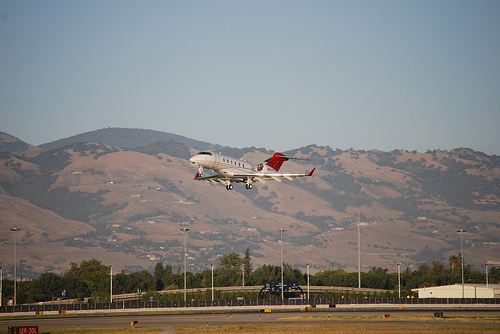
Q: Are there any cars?
A: No, there are no cars.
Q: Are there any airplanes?
A: Yes, there is an airplane.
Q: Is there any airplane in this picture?
A: Yes, there is an airplane.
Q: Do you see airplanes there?
A: Yes, there is an airplane.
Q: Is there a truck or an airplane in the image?
A: Yes, there is an airplane.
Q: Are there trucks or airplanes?
A: Yes, there is an airplane.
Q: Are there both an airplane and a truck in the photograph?
A: No, there is an airplane but no trucks.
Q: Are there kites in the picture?
A: No, there are no kites.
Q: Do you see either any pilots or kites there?
A: No, there are no kites or pilots.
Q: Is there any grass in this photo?
A: Yes, there is grass.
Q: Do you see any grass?
A: Yes, there is grass.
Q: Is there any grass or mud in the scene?
A: Yes, there is grass.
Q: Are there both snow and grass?
A: No, there is grass but no snow.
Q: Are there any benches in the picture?
A: No, there are no benches.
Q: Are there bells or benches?
A: No, there are no benches or bells.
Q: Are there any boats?
A: No, there are no boats.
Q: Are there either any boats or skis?
A: No, there are no boats or skis.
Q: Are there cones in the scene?
A: No, there are no cones.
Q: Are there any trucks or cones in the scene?
A: No, there are no cones or trucks.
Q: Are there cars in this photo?
A: No, there are no cars.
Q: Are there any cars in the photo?
A: No, there are no cars.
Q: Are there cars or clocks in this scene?
A: No, there are no cars or clocks.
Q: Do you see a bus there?
A: No, there are no buses.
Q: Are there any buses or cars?
A: No, there are no buses or cars.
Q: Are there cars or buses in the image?
A: No, there are no buses or cars.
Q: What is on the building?
A: The sign is on the building.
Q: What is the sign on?
A: The sign is on the building.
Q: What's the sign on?
A: The sign is on the building.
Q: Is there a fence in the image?
A: Yes, there is a fence.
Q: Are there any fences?
A: Yes, there is a fence.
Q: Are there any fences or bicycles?
A: Yes, there is a fence.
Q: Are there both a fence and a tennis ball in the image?
A: No, there is a fence but no tennis balls.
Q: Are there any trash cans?
A: No, there are no trash cans.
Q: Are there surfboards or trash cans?
A: No, there are no trash cans or surfboards.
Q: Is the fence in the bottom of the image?
A: Yes, the fence is in the bottom of the image.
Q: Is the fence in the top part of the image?
A: No, the fence is in the bottom of the image.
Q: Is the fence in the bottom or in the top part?
A: The fence is in the bottom of the image.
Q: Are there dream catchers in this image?
A: No, there are no dream catchers.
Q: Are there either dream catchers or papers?
A: No, there are no dream catchers or papers.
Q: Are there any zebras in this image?
A: No, there are no zebras.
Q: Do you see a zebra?
A: No, there are no zebras.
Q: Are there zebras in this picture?
A: No, there are no zebras.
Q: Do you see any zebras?
A: No, there are no zebras.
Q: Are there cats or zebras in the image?
A: No, there are no zebras or cats.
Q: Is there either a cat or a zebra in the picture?
A: No, there are no zebras or cats.